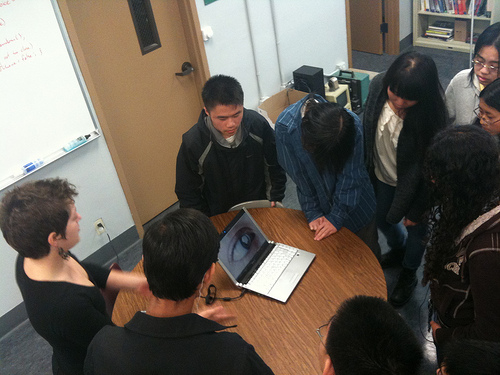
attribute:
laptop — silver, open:
[211, 206, 317, 305]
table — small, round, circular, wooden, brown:
[111, 205, 388, 374]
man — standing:
[173, 72, 287, 219]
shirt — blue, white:
[273, 91, 380, 234]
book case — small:
[412, 2, 500, 54]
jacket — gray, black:
[174, 107, 286, 218]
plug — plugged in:
[97, 223, 103, 230]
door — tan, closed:
[55, 2, 203, 228]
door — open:
[350, 1, 386, 68]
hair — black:
[381, 51, 453, 164]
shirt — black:
[83, 312, 275, 375]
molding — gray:
[242, 1, 288, 100]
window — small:
[128, 0, 163, 57]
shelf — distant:
[411, 1, 499, 51]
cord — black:
[200, 284, 248, 306]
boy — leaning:
[273, 91, 382, 259]